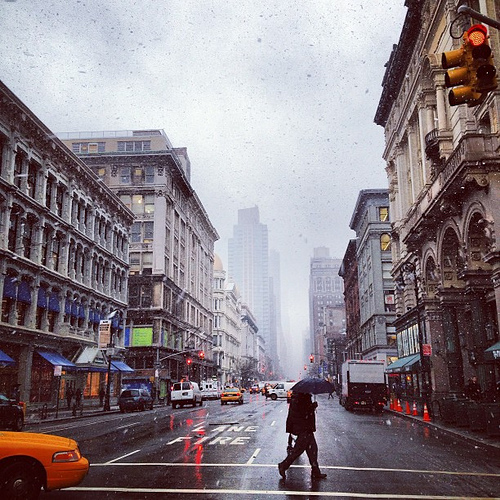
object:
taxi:
[0, 427, 90, 499]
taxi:
[220, 385, 243, 405]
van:
[167, 380, 203, 411]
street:
[4, 380, 499, 498]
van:
[260, 380, 300, 402]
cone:
[421, 403, 431, 423]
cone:
[410, 401, 420, 417]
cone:
[402, 399, 410, 413]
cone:
[395, 397, 403, 413]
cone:
[388, 395, 395, 411]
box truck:
[337, 358, 390, 414]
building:
[375, 3, 498, 443]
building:
[56, 127, 218, 405]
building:
[0, 79, 137, 428]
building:
[225, 204, 274, 383]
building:
[308, 245, 347, 385]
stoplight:
[458, 23, 498, 93]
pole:
[456, 4, 500, 32]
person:
[276, 382, 328, 483]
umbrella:
[291, 375, 337, 397]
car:
[117, 385, 155, 412]